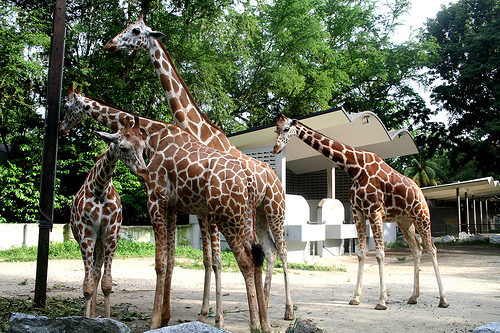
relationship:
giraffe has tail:
[59, 87, 282, 323] [228, 162, 269, 276]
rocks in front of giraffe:
[19, 309, 97, 332] [59, 87, 282, 323]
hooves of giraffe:
[347, 285, 399, 312] [272, 110, 460, 328]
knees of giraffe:
[354, 241, 387, 265] [272, 110, 460, 328]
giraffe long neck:
[59, 87, 282, 323] [86, 98, 159, 138]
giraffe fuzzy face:
[59, 87, 282, 323] [54, 89, 84, 136]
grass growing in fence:
[21, 237, 135, 258] [0, 224, 193, 257]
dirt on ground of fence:
[301, 274, 353, 330] [0, 224, 193, 257]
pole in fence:
[48, 6, 65, 310] [0, 224, 193, 257]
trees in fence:
[9, 18, 37, 221] [0, 224, 193, 257]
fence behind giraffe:
[0, 224, 193, 257] [59, 87, 282, 323]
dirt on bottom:
[301, 274, 353, 330] [0, 245, 499, 331]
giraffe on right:
[272, 110, 460, 328] [303, 9, 497, 319]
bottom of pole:
[23, 262, 69, 316] [48, 6, 65, 310]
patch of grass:
[38, 235, 121, 274] [21, 237, 135, 258]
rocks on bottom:
[19, 309, 97, 332] [0, 245, 499, 331]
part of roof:
[331, 115, 343, 126] [227, 111, 420, 164]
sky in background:
[383, 0, 445, 44] [19, 8, 498, 125]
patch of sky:
[38, 235, 121, 274] [383, 0, 445, 44]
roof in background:
[227, 111, 420, 164] [19, 8, 498, 125]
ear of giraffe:
[149, 30, 170, 42] [59, 87, 282, 323]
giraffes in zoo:
[59, 18, 451, 323] [184, 110, 418, 260]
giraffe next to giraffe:
[60, 121, 149, 332] [59, 87, 282, 323]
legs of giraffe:
[135, 189, 173, 331] [59, 87, 282, 323]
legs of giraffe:
[217, 216, 284, 332] [59, 87, 282, 323]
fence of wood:
[7, 211, 204, 259] [5, 228, 20, 242]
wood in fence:
[5, 228, 20, 242] [0, 224, 193, 257]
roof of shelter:
[227, 111, 420, 164] [183, 105, 424, 275]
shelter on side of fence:
[183, 105, 424, 275] [0, 224, 193, 257]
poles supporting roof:
[450, 192, 500, 245] [407, 172, 500, 205]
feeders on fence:
[280, 207, 367, 247] [0, 224, 193, 257]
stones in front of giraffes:
[15, 304, 217, 333] [59, 18, 451, 323]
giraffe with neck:
[59, 87, 282, 323] [86, 98, 159, 138]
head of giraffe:
[58, 81, 92, 141] [59, 87, 282, 323]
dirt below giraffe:
[301, 274, 353, 330] [59, 87, 282, 323]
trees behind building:
[9, 18, 37, 221] [201, 118, 499, 276]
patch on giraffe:
[69, 197, 120, 225] [59, 87, 282, 323]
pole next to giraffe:
[48, 6, 65, 310] [59, 87, 282, 323]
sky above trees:
[383, 0, 445, 44] [9, 18, 37, 221]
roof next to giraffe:
[227, 111, 420, 164] [59, 87, 282, 323]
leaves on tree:
[2, 29, 26, 59] [9, 18, 37, 221]